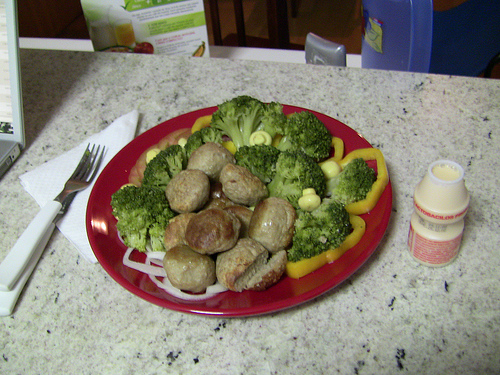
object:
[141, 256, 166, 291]
slices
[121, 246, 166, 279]
onions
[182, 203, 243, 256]
meat ball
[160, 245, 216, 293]
meat ball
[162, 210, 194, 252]
meat ball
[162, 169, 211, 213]
meat ball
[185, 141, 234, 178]
meat ball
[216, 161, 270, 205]
meat ball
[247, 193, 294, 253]
meat ball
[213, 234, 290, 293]
meat balls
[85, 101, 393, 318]
plate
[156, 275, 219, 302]
onions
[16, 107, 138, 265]
napkin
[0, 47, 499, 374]
table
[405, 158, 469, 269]
jug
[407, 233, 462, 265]
writing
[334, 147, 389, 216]
food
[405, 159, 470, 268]
drink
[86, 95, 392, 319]
meal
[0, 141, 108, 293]
utensils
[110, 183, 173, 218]
crown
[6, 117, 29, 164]
corner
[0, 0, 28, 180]
laptop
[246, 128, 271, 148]
mushroom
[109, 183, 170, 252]
broccoli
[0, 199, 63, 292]
handle